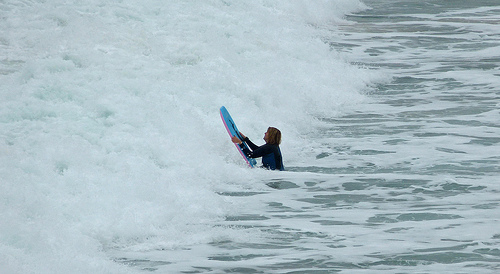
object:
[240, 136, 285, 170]
wetsuit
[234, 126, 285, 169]
person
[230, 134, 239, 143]
hand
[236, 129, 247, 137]
hand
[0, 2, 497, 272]
ocean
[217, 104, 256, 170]
board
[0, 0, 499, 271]
beach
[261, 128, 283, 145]
head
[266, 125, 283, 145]
hair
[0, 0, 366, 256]
wave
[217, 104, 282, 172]
surfing